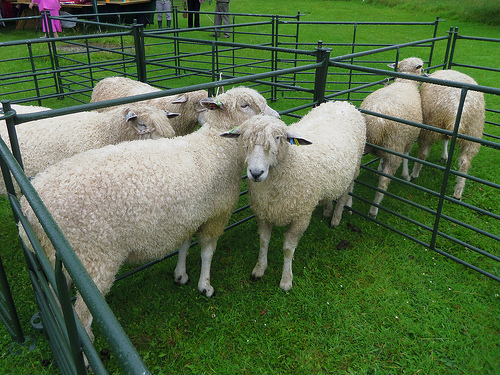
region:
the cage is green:
[446, 172, 485, 272]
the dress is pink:
[29, 1, 76, 36]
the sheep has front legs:
[245, 219, 303, 299]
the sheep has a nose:
[238, 160, 274, 185]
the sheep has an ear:
[276, 115, 318, 153]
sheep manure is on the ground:
[332, 227, 357, 265]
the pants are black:
[185, 1, 204, 26]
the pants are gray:
[210, 0, 240, 40]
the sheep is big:
[62, 90, 244, 307]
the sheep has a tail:
[445, 113, 464, 143]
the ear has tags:
[280, 133, 317, 158]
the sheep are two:
[37, 108, 394, 278]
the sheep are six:
[54, 38, 496, 263]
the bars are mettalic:
[389, 70, 471, 263]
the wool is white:
[287, 110, 382, 197]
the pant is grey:
[207, 3, 249, 45]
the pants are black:
[184, 8, 205, 30]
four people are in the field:
[29, 3, 249, 45]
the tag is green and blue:
[284, 140, 312, 153]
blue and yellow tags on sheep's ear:
[283, 130, 310, 151]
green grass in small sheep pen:
[219, 290, 316, 368]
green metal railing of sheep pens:
[191, 11, 316, 83]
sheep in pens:
[23, 83, 377, 268]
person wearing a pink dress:
[34, 0, 62, 36]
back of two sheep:
[373, 55, 487, 205]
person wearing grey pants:
[205, 0, 240, 40]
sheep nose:
[247, 165, 267, 179]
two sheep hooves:
[247, 245, 302, 299]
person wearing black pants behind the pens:
[177, 0, 204, 32]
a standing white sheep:
[15, 80, 282, 370]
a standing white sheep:
[221, 96, 361, 291]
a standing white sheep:
[360, 55, 425, 216]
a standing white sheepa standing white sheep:
[0, 101, 172, 181]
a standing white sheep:
[91, 70, 206, 140]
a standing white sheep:
[405, 65, 483, 203]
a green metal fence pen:
[2, 58, 494, 369]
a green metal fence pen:
[323, 28, 498, 280]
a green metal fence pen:
[0, 23, 320, 165]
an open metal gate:
[273, 11, 440, 103]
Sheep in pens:
[36, 71, 491, 272]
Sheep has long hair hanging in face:
[222, 118, 297, 180]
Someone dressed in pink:
[30, 0, 72, 39]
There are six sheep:
[47, 28, 477, 293]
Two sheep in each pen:
[22, 49, 483, 174]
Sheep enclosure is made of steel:
[138, 6, 493, 264]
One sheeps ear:
[275, 132, 315, 158]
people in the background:
[95, 0, 251, 40]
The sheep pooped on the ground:
[330, 208, 378, 283]